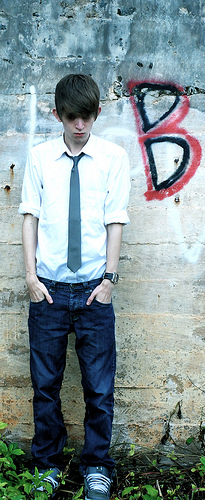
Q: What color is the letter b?
A: Red, black.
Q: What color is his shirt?
A: White.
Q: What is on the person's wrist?
A: Watch.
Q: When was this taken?
A: Daytime.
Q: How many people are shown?
A: 1.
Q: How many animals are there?
A: 0.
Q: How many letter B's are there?
A: 2.